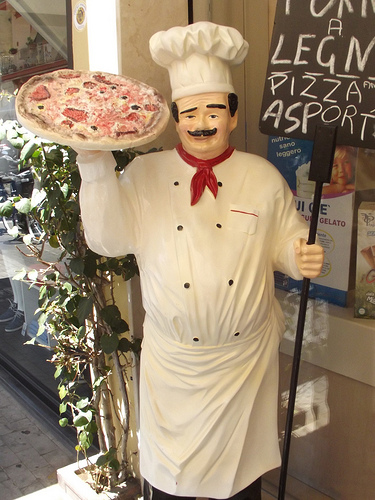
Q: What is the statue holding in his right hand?
A: Pizza.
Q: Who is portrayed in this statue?
A: Chef.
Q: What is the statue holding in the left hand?
A: Sign.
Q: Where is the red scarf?
A: Around his neck.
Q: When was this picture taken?
A: Daytime.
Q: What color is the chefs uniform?
A: White.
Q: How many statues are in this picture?
A: One.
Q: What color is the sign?
A: Black.